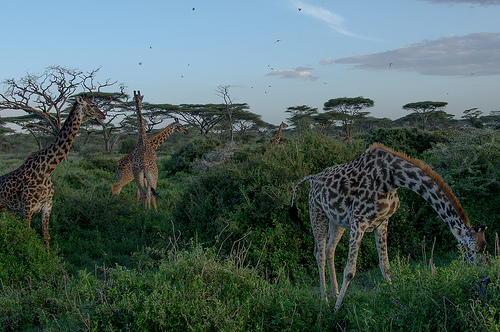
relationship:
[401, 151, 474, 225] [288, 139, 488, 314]
neck of nearest giraffe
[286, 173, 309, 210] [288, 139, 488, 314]
tail of nearest giraffe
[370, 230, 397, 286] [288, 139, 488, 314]
leg of nearest giraffe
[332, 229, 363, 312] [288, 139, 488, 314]
leg of nearest giraffe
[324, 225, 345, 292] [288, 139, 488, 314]
leg of nearest giraffe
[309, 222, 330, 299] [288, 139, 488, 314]
leg of nearest giraffe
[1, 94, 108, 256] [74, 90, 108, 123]
giraffe with a visible head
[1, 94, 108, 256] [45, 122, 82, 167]
giraffe with a visible neck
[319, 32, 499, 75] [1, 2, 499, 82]
cloud in sky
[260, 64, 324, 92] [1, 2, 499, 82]
cloud in sky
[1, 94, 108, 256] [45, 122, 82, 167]
giraffe has a neck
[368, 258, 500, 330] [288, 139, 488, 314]
grass surrounding giraffe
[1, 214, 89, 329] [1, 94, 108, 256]
bush surrounding giraffe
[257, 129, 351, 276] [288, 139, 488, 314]
bush surrounding giraffe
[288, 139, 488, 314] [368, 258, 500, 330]
giraffe grazing in bush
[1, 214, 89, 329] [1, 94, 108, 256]
foliage for giraffe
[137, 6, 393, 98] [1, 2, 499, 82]
birds flying in sky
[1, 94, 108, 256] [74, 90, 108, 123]
giraffe has a visible head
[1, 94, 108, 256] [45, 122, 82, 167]
giraffe has a visible neck